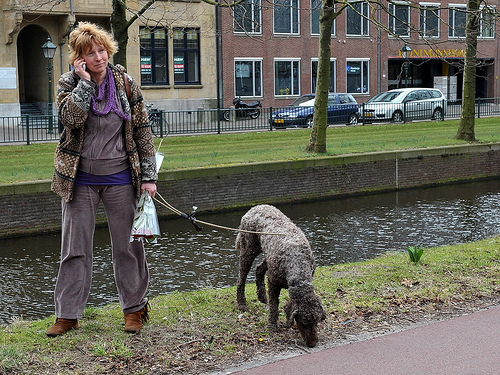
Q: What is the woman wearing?
A: A scarf around her neck.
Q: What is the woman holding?
A: A dog leash.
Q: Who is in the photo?
A: A woman and her dog.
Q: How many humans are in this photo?
A: Only one.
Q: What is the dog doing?
A: Sniffing the ground.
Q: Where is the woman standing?
A: In the grass.